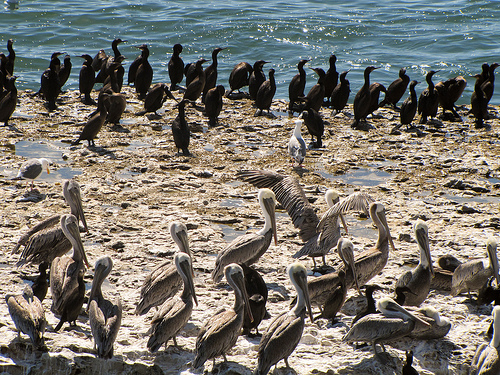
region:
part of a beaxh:
[210, 166, 234, 200]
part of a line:
[286, 303, 297, 322]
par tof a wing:
[311, 273, 338, 303]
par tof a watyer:
[211, 215, 240, 256]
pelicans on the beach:
[6, 159, 498, 371]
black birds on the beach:
[5, 33, 497, 150]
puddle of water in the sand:
[15, 138, 82, 180]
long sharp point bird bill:
[72, 188, 91, 237]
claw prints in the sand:
[114, 269, 159, 370]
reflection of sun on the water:
[251, 18, 339, 48]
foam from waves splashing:
[387, 61, 464, 76]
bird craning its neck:
[95, 35, 130, 80]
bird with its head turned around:
[3, 280, 48, 352]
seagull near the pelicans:
[287, 115, 308, 169]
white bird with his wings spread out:
[239, 153, 374, 265]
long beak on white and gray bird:
[293, 276, 322, 330]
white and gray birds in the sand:
[115, 194, 341, 354]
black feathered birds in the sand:
[38, 42, 494, 132]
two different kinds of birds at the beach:
[67, 20, 404, 330]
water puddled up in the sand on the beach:
[320, 146, 477, 207]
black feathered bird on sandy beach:
[142, 79, 176, 116]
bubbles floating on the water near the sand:
[280, 15, 416, 110]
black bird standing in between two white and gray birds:
[196, 186, 282, 371]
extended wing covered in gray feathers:
[309, 185, 381, 240]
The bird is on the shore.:
[163, 98, 202, 168]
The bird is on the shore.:
[275, 113, 332, 175]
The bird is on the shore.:
[68, 87, 123, 162]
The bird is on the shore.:
[201, 173, 283, 288]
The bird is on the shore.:
[246, 254, 326, 374]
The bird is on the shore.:
[183, 257, 260, 372]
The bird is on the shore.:
[140, 245, 210, 371]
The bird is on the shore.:
[75, 245, 152, 370]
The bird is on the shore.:
[5, 276, 73, 371]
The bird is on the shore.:
[443, 225, 499, 312]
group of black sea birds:
[0, 28, 499, 167]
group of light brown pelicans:
[2, 168, 496, 374]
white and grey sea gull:
[282, 112, 312, 167]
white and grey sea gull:
[9, 156, 55, 193]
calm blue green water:
[0, 0, 498, 106]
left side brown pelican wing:
[233, 163, 320, 237]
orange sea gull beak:
[41, 163, 55, 178]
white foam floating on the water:
[225, 13, 465, 80]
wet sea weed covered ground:
[0, 80, 499, 370]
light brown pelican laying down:
[385, 298, 460, 343]